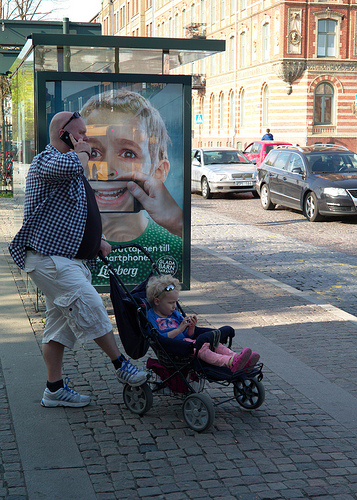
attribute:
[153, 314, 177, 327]
shirt — blue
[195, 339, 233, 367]
pants — pink 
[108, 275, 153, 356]
bag — black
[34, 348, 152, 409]
shoes — white 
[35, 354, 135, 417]
socks — Black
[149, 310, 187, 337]
shirt — blue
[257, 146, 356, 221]
car —  black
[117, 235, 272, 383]
girl — Little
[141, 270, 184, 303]
hair — Blonde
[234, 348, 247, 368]
shoe — pink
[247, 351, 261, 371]
shoe — pink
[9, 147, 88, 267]
shirt — checkered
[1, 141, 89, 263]
shirt — black, white, checkered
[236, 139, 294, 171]
car —  red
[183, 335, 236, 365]
pants — pink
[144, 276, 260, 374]
kid — small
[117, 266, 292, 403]
girl — little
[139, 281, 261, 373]
girl — little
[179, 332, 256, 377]
pants — pink